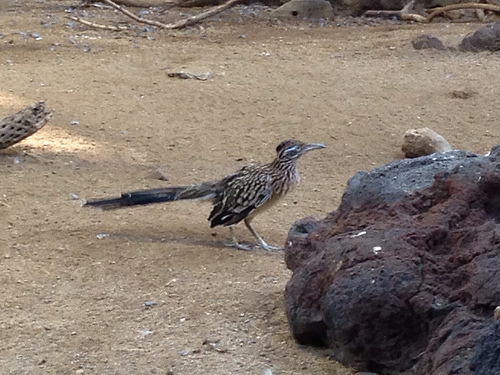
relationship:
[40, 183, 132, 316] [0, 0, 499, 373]
part of a beach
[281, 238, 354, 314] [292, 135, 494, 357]
part of a rock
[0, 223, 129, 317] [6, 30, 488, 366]
part of a ground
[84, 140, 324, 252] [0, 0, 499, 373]
bird walking beach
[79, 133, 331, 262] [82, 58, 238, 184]
bird finding its nest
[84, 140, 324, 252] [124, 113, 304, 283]
bird looking for its mate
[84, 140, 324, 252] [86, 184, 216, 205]
bird has colorful tailfeather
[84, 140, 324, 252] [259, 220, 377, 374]
bird close to a rock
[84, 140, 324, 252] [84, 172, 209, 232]
bird has long tail feathers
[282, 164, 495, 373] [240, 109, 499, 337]
large gray lava rock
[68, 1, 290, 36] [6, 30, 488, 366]
branch on ground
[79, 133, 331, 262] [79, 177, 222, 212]
bird has a long black tailfeather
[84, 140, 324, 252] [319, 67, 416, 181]
bird looking up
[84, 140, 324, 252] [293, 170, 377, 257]
bird looking up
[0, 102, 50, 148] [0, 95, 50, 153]
skeleton of ocotillo cactus skeleton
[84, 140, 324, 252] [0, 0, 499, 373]
bird bird in beach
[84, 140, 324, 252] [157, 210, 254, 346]
bird tail used to balance while running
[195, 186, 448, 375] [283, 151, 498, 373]
dark desert rock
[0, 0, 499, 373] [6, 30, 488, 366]
beach floor dirt ground